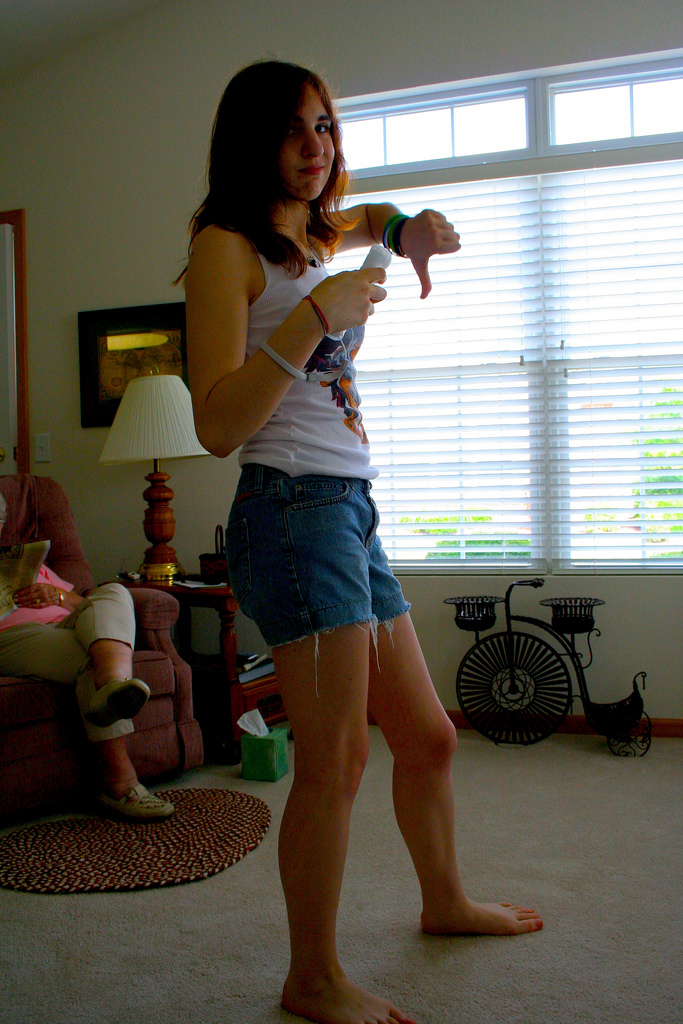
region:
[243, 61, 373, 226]
the head of a young woman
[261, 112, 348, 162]
the eyes of a young woman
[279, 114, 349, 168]
the nose of a young woman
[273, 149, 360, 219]
the mouth of a young woman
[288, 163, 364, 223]
the chin of a young woman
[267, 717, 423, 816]
the knee of a young woman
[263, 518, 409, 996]
the leg of a young woman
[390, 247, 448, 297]
the thumb of a young woman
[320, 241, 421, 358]
the fingers of a young woman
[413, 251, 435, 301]
Thumb is pointing down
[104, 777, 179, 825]
Foot resting on a mat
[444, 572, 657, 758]
Tricycle decor by the window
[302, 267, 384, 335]
Hand holding white Wii remote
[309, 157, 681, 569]
White blinds over the window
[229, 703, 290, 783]
Green tissue box near the mat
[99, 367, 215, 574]
Lamp sitting on an accent table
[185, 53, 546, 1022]
Woman is wearing jean shorts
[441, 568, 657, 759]
Tricycle decor is black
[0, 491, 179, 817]
Woman reading the newspaper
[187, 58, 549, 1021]
woman has bare feet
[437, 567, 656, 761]
wrought iron vintage bicycle planter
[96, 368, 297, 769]
wooden lamp on wood end table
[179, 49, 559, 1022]
woman is wearing blue jeans shorts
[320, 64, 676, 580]
white mini blinds on window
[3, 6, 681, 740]
black framed artwork on cream colored wall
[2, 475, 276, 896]
woman's foot is on the red woven rug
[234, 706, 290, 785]
green tissue box has white tissue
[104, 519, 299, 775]
basket on end table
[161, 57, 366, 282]
long brown hair on a girl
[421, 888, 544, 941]
a left bare foot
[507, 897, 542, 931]
toes on a foot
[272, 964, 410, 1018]
a right bare foot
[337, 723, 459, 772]
a young girl's kneecaps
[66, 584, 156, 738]
a tan pair of chinos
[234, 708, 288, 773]
a green tissue box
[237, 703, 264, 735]
a white tissue in a box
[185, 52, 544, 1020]
woman standing in the living room wearing denim shorts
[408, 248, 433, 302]
thumb is pointing down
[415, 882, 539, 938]
foot on white carpet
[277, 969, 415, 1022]
foot on white carpet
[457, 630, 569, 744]
wheel belongs to cart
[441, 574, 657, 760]
black cart on white carpet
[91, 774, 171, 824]
shoe worn on foot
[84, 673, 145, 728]
shoe worn on foot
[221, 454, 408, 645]
denim shorts worn by human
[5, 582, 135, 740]
beige pants worn by human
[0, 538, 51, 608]
newspaper held by human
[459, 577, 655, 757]
a bicycle shaped planter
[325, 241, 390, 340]
a Wii video game controller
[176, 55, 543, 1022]
a girl playing a video game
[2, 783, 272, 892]
a small floor mat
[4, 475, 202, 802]
a maroon arm chair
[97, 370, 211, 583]
a brown table lamp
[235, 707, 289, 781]
a box of facial tissue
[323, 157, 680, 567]
a set of venetian blinds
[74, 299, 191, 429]
a framed print on wall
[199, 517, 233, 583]
a small basket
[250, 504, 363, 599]
women is wearing shorts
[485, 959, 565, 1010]
the carpet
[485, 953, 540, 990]
the carpet is brown